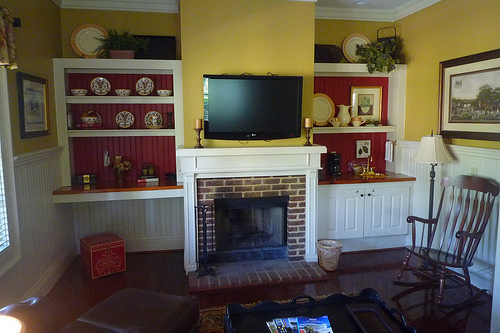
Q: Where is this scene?
A: A living room.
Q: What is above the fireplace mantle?
A: A television.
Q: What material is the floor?
A: Wood.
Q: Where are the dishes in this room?
A: On the shelfs.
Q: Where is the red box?
A: In front of the left shelf.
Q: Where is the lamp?
A: Behind the rocking chair.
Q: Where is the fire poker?
A: On the left side of the dire place.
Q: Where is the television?
A: On the yellow wall.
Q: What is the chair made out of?
A: Wood.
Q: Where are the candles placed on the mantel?
A: On the sides.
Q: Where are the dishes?
A: On the shelves.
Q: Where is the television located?
A: Over the mantel.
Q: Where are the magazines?
A: On the coffee table.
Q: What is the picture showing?
A: A living room.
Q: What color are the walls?
A: Yellow.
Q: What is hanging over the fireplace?
A: A television.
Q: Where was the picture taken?
A: In a living room.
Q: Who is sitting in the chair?
A: No one.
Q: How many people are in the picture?
A: None.